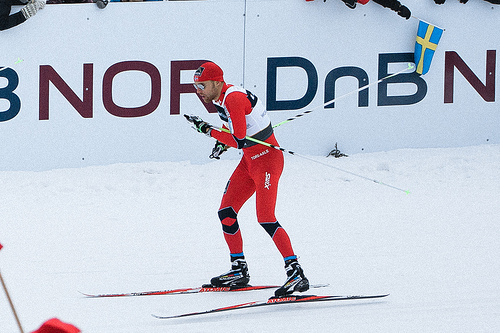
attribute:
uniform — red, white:
[184, 57, 314, 319]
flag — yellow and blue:
[409, 16, 446, 74]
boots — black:
[207, 245, 306, 297]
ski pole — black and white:
[189, 119, 418, 199]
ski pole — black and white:
[272, 60, 412, 132]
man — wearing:
[182, 47, 331, 316]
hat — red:
[192, 60, 221, 82]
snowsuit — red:
[217, 82, 294, 259]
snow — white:
[6, 138, 496, 330]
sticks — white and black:
[182, 71, 414, 193]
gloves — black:
[173, 108, 228, 162]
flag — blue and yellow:
[403, 10, 445, 74]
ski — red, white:
[156, 291, 391, 331]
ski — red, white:
[84, 273, 334, 300]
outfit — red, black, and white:
[202, 81, 300, 263]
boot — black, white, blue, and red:
[272, 256, 309, 303]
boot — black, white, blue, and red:
[211, 260, 249, 290]